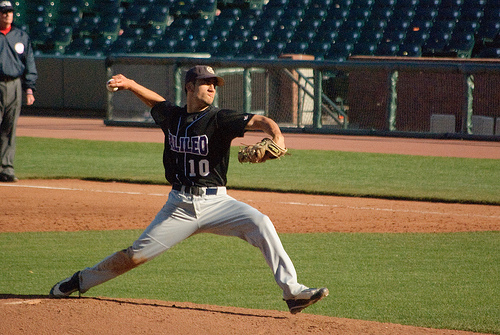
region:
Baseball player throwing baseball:
[52, 63, 337, 324]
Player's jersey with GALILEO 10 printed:
[162, 122, 214, 179]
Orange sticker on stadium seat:
[407, 24, 422, 36]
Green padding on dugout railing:
[97, 52, 490, 150]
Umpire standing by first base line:
[0, 1, 39, 186]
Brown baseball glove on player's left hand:
[239, 130, 286, 173]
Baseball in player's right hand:
[102, 68, 127, 98]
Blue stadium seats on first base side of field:
[23, 1, 498, 63]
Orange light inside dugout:
[335, 109, 347, 124]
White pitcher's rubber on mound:
[1, 287, 51, 318]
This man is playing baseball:
[62, 55, 319, 317]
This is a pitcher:
[71, 65, 316, 302]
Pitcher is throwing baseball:
[97, 58, 285, 175]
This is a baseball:
[97, 59, 136, 101]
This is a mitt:
[229, 125, 290, 173]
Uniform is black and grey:
[128, 96, 255, 243]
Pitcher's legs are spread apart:
[22, 205, 357, 331]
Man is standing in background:
[0, 0, 40, 187]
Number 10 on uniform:
[182, 155, 222, 177]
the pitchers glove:
[238, 138, 291, 172]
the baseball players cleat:
[263, 280, 335, 312]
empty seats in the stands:
[287, 7, 347, 43]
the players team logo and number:
[156, 99, 237, 184]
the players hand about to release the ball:
[102, 63, 132, 100]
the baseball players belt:
[159, 172, 234, 208]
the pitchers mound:
[2, 285, 50, 312]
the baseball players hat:
[175, 57, 223, 87]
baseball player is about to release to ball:
[68, 22, 324, 313]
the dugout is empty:
[260, 63, 452, 150]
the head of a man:
[161, 49, 234, 117]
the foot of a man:
[41, 259, 110, 307]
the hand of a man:
[91, 60, 140, 112]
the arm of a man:
[78, 6, 198, 201]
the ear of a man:
[183, 65, 209, 107]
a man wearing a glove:
[224, 95, 314, 185]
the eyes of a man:
[191, 56, 229, 116]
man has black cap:
[176, 69, 219, 81]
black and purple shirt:
[143, 91, 238, 187]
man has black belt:
[173, 187, 223, 204]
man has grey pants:
[88, 194, 302, 308]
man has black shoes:
[271, 286, 326, 320]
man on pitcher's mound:
[8, 271, 72, 316]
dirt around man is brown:
[66, 294, 256, 325]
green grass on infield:
[319, 245, 449, 298]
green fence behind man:
[144, 42, 494, 137]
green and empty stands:
[53, 1, 473, 70]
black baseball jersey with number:
[149, 95, 266, 187]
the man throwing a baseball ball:
[50, 65, 328, 314]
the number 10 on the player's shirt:
[186, 158, 211, 178]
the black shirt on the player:
[150, 98, 255, 186]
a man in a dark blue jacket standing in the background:
[0, 0, 37, 182]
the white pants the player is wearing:
[78, 183, 309, 300]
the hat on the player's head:
[183, 65, 225, 88]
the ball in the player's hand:
[105, 77, 118, 92]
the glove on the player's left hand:
[237, 138, 286, 165]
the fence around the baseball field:
[21, 50, 499, 142]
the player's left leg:
[223, 197, 328, 316]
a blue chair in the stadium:
[401, 19, 414, 39]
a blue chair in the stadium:
[472, 34, 486, 53]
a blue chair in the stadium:
[462, 19, 479, 42]